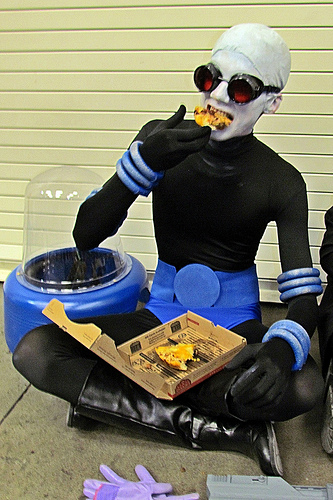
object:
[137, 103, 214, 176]
glove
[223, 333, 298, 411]
glove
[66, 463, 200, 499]
gloves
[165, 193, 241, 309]
stomach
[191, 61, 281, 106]
goggles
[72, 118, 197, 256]
arm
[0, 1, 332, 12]
line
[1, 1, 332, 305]
door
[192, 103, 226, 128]
food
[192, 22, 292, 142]
person dressed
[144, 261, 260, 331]
shorts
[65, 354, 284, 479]
boot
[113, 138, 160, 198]
bracelet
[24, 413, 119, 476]
pavement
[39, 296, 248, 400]
box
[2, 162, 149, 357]
helmet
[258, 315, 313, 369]
bracelets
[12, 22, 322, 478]
girl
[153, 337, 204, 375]
food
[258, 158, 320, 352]
arm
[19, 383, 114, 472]
patch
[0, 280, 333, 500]
concrete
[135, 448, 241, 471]
patch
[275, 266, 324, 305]
bracelets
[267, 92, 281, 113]
ear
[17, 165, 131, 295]
case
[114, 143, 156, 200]
wrist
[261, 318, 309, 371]
wrist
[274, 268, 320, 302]
wrist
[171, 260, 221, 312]
circle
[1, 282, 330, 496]
ground